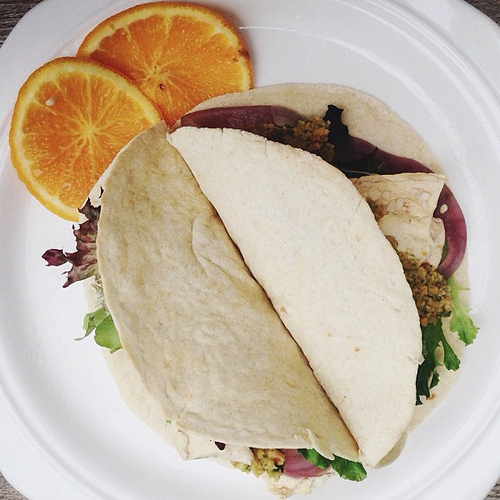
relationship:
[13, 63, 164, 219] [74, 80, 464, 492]
orange slice beside tacos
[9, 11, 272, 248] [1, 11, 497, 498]
oranges on plate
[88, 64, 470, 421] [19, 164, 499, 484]
food on plate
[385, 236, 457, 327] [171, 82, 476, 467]
meat on taco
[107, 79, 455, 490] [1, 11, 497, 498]
tacos on plate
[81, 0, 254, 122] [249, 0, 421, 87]
orange slice on plate